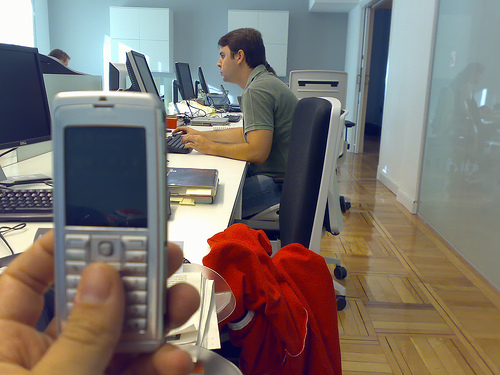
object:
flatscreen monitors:
[124, 49, 209, 100]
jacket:
[202, 223, 342, 375]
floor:
[318, 123, 500, 375]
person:
[0, 90, 200, 375]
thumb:
[29, 262, 124, 375]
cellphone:
[49, 90, 168, 354]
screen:
[175, 62, 196, 100]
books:
[166, 167, 219, 206]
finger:
[162, 282, 202, 337]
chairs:
[232, 96, 356, 311]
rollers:
[308, 183, 343, 312]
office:
[0, 0, 500, 375]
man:
[172, 28, 299, 178]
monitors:
[0, 49, 210, 151]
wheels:
[334, 266, 347, 311]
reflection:
[429, 63, 500, 208]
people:
[47, 28, 299, 217]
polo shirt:
[241, 64, 299, 177]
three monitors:
[124, 48, 209, 96]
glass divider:
[413, 0, 500, 291]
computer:
[124, 50, 161, 98]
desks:
[0, 112, 248, 375]